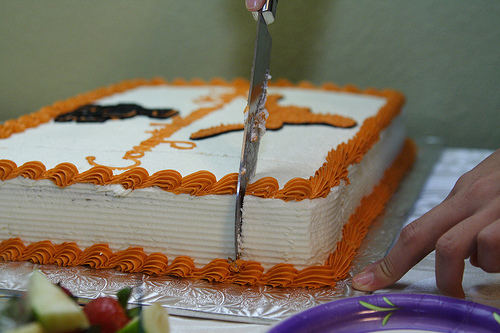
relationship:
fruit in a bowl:
[2, 268, 170, 332] [1, 287, 113, 332]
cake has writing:
[2, 77, 418, 289] [85, 86, 249, 174]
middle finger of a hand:
[349, 192, 481, 289] [354, 150, 499, 300]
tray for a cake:
[2, 130, 446, 321] [2, 77, 418, 289]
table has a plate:
[2, 146, 496, 333] [266, 292, 497, 331]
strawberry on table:
[83, 294, 130, 332] [2, 146, 496, 333]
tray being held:
[2, 130, 446, 321] [349, 192, 481, 289]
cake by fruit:
[2, 77, 418, 289] [2, 268, 170, 332]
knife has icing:
[233, 0, 287, 268] [232, 72, 267, 256]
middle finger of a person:
[349, 192, 481, 289] [354, 150, 499, 300]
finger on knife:
[243, 0, 274, 10] [233, 0, 287, 268]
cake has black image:
[2, 77, 418, 289] [57, 102, 182, 122]